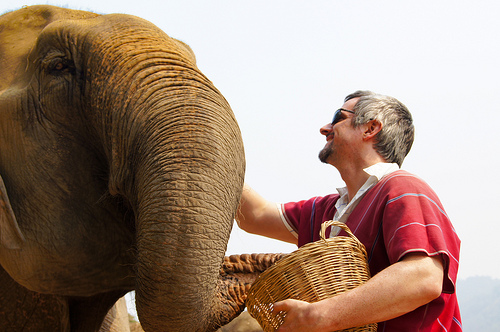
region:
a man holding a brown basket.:
[227, 89, 468, 330]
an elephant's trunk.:
[81, 37, 313, 329]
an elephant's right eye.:
[26, 51, 102, 96]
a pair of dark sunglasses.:
[321, 102, 349, 134]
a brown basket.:
[235, 219, 383, 326]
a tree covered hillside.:
[453, 273, 497, 330]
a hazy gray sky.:
[0, 3, 497, 278]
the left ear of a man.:
[352, 117, 392, 153]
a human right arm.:
[224, 193, 332, 248]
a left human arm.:
[274, 254, 454, 329]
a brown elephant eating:
[0, 7, 245, 330]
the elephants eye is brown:
[41, 53, 73, 78]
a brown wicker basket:
[245, 219, 375, 330]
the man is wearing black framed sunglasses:
[330, 107, 362, 122]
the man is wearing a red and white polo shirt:
[280, 160, 464, 330]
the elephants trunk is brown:
[101, 63, 249, 330]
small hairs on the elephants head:
[0, 1, 101, 12]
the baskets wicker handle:
[318, 216, 358, 241]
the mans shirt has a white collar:
[361, 160, 400, 180]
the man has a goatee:
[315, 139, 336, 163]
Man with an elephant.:
[44, 12, 459, 326]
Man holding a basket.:
[226, 66, 375, 281]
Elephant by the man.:
[47, 22, 451, 254]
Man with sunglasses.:
[305, 95, 432, 193]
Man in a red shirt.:
[264, 76, 494, 311]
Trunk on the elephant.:
[102, 46, 300, 328]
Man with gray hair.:
[290, 80, 475, 197]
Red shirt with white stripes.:
[328, 133, 450, 269]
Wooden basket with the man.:
[257, 212, 358, 328]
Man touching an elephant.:
[230, 86, 459, 276]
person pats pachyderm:
[0, 3, 477, 328]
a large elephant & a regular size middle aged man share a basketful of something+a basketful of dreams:
[0, 6, 477, 329]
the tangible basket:
[241, 210, 381, 329]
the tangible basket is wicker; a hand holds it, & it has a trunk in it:
[238, 212, 374, 328]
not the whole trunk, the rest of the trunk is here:
[106, 55, 302, 328]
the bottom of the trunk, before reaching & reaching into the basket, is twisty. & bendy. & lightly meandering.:
[131, 241, 301, 330]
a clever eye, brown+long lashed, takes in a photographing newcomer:
[31, 42, 83, 88]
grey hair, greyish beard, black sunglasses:
[307, 83, 412, 179]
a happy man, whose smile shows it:
[308, 121, 344, 161]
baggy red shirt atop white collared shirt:
[244, 158, 477, 329]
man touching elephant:
[15, 54, 440, 301]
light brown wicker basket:
[255, 224, 376, 324]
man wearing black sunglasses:
[306, 71, 425, 176]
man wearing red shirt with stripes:
[273, 161, 483, 323]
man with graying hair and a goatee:
[305, 83, 423, 180]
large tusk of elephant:
[136, 48, 260, 325]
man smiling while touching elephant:
[206, 68, 433, 249]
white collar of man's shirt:
[314, 153, 409, 225]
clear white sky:
[243, 13, 418, 74]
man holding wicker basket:
[243, 87, 439, 325]